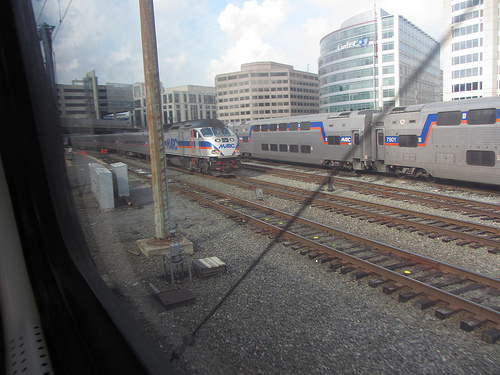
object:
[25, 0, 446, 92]
sky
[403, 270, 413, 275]
yellow dots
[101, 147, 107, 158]
cones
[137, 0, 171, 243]
pole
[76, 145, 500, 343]
tracks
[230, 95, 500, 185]
car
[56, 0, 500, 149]
building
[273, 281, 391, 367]
gravel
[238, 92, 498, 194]
engine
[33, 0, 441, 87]
clouds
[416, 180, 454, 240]
ground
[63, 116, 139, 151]
tunnel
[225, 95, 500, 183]
double decker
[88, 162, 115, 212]
boxes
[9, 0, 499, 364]
window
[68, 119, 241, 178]
train car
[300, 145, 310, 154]
windows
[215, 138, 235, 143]
black writing